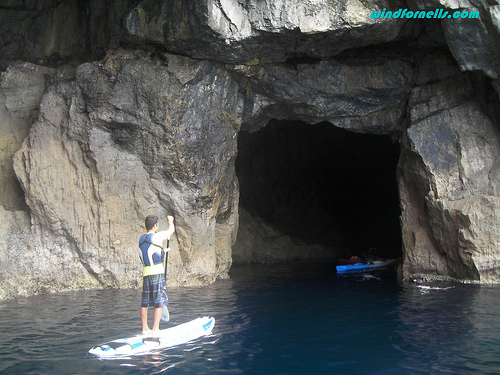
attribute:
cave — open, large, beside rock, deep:
[21, 8, 489, 298]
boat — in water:
[333, 251, 388, 274]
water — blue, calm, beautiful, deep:
[44, 265, 412, 368]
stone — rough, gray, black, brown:
[175, 138, 232, 267]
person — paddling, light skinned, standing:
[134, 214, 174, 336]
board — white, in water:
[92, 319, 215, 364]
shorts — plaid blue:
[142, 277, 166, 307]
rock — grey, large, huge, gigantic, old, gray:
[405, 133, 472, 247]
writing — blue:
[370, 5, 485, 24]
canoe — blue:
[337, 256, 391, 282]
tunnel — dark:
[250, 126, 401, 277]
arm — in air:
[162, 213, 182, 234]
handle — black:
[166, 218, 173, 260]